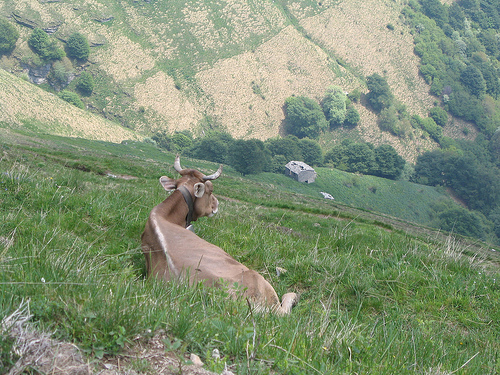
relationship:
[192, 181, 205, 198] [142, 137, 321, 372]
ear on cow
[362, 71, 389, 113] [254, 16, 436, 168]
tree in field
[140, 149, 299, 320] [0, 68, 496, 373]
cow on grass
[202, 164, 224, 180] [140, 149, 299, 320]
horn of cow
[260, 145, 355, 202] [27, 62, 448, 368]
house in field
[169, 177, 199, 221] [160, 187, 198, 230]
collar around neck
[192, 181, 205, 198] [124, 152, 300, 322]
ear of cow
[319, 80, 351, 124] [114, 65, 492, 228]
tree in field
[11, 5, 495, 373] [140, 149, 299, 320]
hillside with cow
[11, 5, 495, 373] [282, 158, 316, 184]
hillside with house